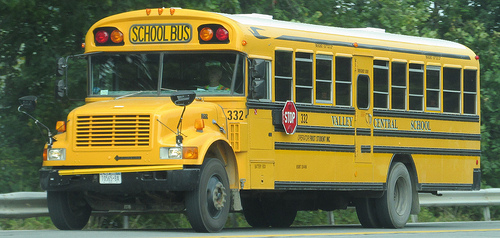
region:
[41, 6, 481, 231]
a yellow school bus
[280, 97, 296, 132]
a stop sign on the side of the school bus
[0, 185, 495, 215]
a guard rail by the school bus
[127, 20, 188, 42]
words above the bus's windshield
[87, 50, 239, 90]
front windshield of the school bus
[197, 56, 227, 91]
driver behind the windshield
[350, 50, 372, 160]
door on the side of the school bus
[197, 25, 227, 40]
round orange and red lights above the bus driver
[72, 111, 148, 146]
front grill on the school bus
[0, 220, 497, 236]
road the school bus is on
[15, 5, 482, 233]
A yellow school bus.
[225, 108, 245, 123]
The bus number is 332.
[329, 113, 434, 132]
The bus serves Valley Central School.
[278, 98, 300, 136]
The stop sign is not deployed.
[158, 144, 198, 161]
Right headlight.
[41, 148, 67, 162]
Left headlight.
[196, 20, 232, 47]
Warning light.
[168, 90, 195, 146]
Rear view mirror.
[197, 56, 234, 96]
A man is driving the bus.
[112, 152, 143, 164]
A black arrow points toward Entrance/Exit.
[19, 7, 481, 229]
the yellow school bus on the road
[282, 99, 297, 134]
the red STOP sign on the side of the bus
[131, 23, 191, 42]
the words SCHOOL BUS on the front of the bus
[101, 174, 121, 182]
the license plate in the front of the bus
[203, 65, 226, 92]
the driver in the bus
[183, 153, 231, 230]
the front tire on the driver's side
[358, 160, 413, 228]
the back tires on the driver's side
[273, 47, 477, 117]
the passenger windows on the driver's side of the bus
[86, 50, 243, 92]
the windshield of the bus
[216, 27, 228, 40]
the red light on the front of the bus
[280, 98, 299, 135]
a red stop sign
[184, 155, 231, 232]
front driver side tire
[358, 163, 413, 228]
rear driver side tire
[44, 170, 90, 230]
front passenger side tire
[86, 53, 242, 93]
front bus glass windshield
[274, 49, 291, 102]
an open passenger window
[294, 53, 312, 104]
an open passenger window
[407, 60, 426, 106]
an open passenger window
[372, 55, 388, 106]
an open passenger window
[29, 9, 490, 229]
yellow and black school bus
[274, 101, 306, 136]
red and white stop sign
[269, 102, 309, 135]
stop sign on the side of the bus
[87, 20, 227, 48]
lights on top of the bus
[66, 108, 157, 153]
lines on the front of the bus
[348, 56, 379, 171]
emergency exit door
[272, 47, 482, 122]
row of dark windows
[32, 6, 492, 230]
bus on the street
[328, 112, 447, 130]
writing on the side of the bus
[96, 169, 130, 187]
white license plate